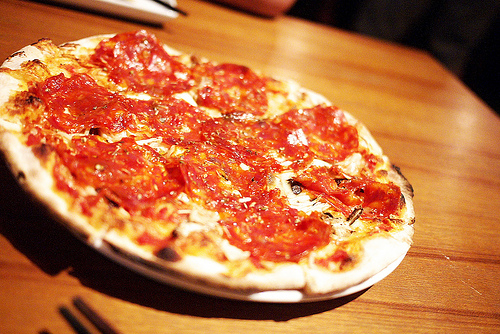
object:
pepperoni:
[138, 116, 308, 191]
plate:
[2, 32, 414, 303]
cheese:
[250, 189, 332, 231]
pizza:
[0, 30, 413, 305]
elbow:
[98, 32, 161, 54]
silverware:
[35, 290, 126, 333]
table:
[6, 11, 493, 327]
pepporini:
[195, 119, 274, 163]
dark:
[436, 248, 488, 267]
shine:
[385, 55, 453, 119]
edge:
[302, 18, 436, 59]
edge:
[343, 272, 405, 293]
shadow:
[0, 208, 55, 285]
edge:
[54, 287, 89, 316]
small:
[186, 159, 267, 195]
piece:
[271, 113, 356, 158]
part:
[315, 238, 410, 285]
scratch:
[457, 272, 485, 299]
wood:
[418, 125, 486, 164]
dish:
[198, 287, 301, 316]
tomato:
[323, 250, 353, 263]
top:
[51, 42, 358, 253]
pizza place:
[56, 40, 483, 309]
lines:
[425, 300, 495, 309]